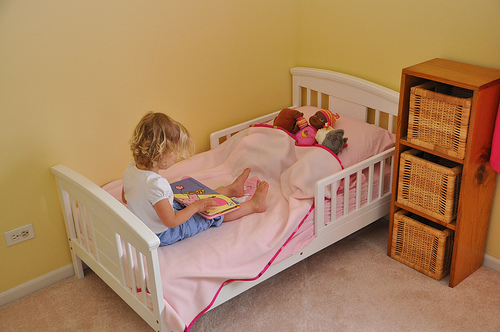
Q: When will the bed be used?
A: Now.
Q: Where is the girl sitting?
A: On the bed.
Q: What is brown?
A: Shelf.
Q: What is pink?
A: Blanket.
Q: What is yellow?
A: Wall.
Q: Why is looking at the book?
A: Reading.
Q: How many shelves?
A: Three.